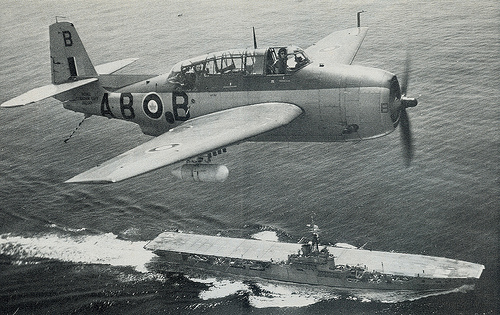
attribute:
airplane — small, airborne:
[10, 16, 469, 216]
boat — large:
[143, 218, 486, 306]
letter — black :
[170, 89, 192, 126]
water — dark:
[3, 3, 497, 313]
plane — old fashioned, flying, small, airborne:
[7, 7, 419, 172]